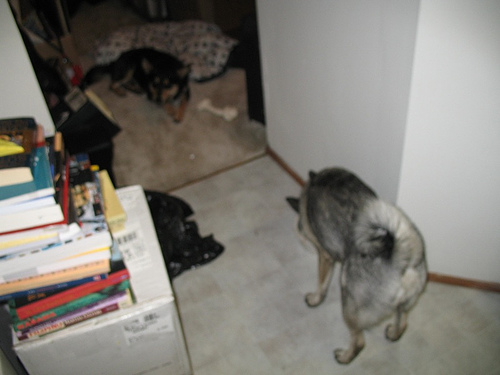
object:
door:
[9, 2, 270, 202]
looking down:
[284, 169, 315, 254]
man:
[76, 45, 195, 121]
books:
[0, 105, 173, 345]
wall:
[273, 26, 400, 149]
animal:
[285, 166, 427, 366]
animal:
[75, 46, 191, 122]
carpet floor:
[30, 2, 272, 195]